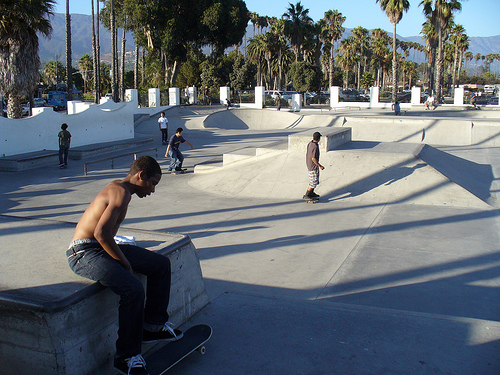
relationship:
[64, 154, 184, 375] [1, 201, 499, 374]
boy on street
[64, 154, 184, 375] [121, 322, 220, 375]
boy with skateboard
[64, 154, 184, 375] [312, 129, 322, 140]
boy with cap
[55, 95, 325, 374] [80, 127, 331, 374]
boys with skateboards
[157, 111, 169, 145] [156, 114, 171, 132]
boy with shirt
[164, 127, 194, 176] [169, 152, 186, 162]
teenager with knees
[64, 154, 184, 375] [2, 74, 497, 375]
boy in park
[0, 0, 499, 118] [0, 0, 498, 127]
trees in background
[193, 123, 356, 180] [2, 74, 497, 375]
stairs in park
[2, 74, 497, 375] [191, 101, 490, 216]
park has ramps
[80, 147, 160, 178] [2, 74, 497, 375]
rail in park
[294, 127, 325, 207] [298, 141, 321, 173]
boy wearing shirt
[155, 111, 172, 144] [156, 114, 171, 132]
boy wearing shirt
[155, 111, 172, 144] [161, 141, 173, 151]
boy on skateboard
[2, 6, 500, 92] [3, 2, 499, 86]
hills in distance